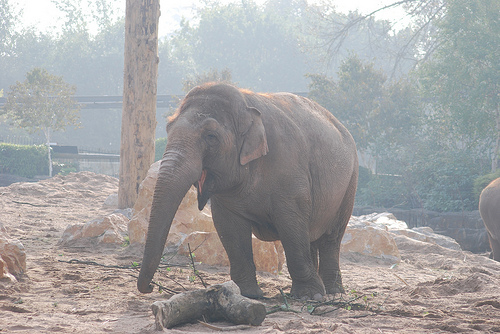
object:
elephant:
[478, 177, 499, 262]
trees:
[163, 0, 500, 214]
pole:
[118, 0, 160, 207]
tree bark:
[124, 16, 153, 149]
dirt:
[3, 250, 144, 312]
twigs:
[301, 286, 387, 319]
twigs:
[187, 241, 207, 291]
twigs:
[128, 274, 179, 295]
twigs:
[198, 314, 262, 331]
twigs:
[59, 258, 141, 268]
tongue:
[197, 168, 207, 193]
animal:
[134, 79, 358, 302]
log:
[150, 284, 267, 331]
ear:
[239, 106, 269, 165]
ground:
[2, 172, 496, 329]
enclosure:
[0, 99, 497, 333]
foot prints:
[54, 271, 90, 297]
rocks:
[348, 211, 462, 258]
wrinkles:
[158, 144, 190, 175]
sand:
[351, 256, 474, 333]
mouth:
[184, 163, 215, 212]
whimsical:
[191, 166, 265, 255]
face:
[184, 110, 244, 181]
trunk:
[135, 152, 203, 294]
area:
[9, 166, 499, 332]